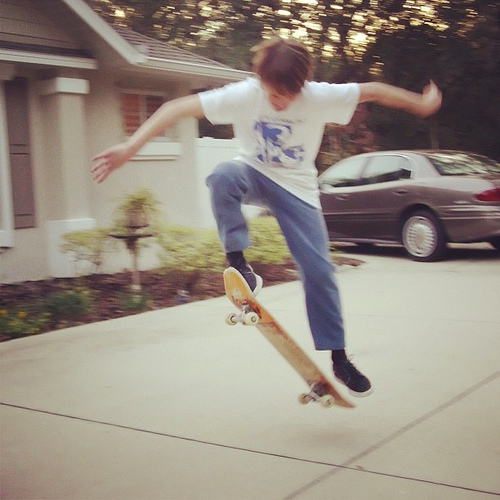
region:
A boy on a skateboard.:
[83, 15, 423, 445]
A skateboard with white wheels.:
[211, 255, 359, 422]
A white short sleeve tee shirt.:
[189, 57, 352, 192]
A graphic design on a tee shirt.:
[219, 99, 327, 177]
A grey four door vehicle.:
[321, 139, 494, 258]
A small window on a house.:
[96, 80, 187, 158]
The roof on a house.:
[123, 23, 218, 63]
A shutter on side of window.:
[3, 77, 44, 231]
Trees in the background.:
[343, 20, 477, 147]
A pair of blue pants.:
[205, 142, 352, 352]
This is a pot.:
[90, 181, 187, 307]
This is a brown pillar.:
[123, 234, 157, 300]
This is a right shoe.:
[214, 234, 271, 309]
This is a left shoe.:
[296, 314, 390, 416]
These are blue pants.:
[194, 145, 381, 364]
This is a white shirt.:
[196, 56, 387, 227]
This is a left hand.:
[79, 126, 175, 196]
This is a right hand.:
[403, 70, 473, 142]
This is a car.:
[299, 131, 496, 265]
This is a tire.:
[396, 193, 456, 274]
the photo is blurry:
[13, 7, 457, 492]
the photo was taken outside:
[10, 23, 495, 496]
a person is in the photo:
[63, 24, 437, 420]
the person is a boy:
[74, 15, 499, 473]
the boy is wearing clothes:
[176, 30, 423, 468]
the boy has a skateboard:
[183, 252, 440, 435]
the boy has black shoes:
[328, 347, 378, 494]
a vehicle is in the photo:
[328, 149, 498, 241]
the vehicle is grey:
[324, 138, 497, 247]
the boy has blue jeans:
[186, 142, 412, 378]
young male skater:
[88, 36, 445, 430]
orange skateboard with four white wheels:
[220, 260, 356, 411]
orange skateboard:
[212, 265, 354, 419]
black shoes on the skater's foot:
[329, 349, 371, 396]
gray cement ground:
[2, 346, 276, 498]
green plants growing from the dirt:
[0, 304, 45, 332]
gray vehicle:
[315, 143, 499, 262]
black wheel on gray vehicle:
[388, 208, 451, 263]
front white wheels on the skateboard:
[225, 309, 263, 326]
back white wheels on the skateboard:
[298, 389, 335, 409]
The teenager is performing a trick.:
[90, 26, 430, 406]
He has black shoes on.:
[317, 345, 397, 415]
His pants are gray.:
[182, 30, 393, 396]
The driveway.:
[5, 255, 495, 495]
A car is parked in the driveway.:
[290, 145, 495, 255]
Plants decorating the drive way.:
[0, 202, 301, 342]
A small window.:
[115, 82, 175, 142]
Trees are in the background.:
[200, 5, 492, 162]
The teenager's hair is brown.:
[245, 20, 306, 115]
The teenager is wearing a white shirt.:
[185, 80, 375, 208]